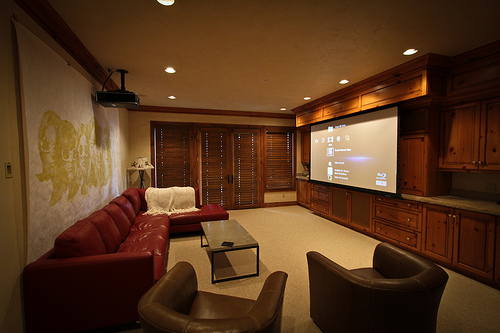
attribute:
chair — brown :
[279, 229, 476, 323]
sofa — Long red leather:
[21, 185, 227, 330]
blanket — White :
[144, 185, 199, 215]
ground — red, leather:
[398, 163, 441, 201]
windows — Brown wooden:
[149, 118, 296, 220]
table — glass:
[188, 216, 275, 282]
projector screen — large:
[305, 103, 402, 197]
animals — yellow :
[17, 52, 139, 222]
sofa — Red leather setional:
[15, 179, 233, 315]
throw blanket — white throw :
[139, 183, 203, 218]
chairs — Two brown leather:
[130, 234, 455, 331]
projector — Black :
[95, 67, 139, 109]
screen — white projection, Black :
[303, 117, 412, 194]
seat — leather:
[305, 238, 451, 330]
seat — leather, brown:
[137, 261, 291, 332]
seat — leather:
[19, 184, 227, 326]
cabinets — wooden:
[288, 52, 499, 287]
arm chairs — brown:
[135, 240, 449, 330]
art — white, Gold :
[20, 43, 129, 189]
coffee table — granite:
[198, 213, 268, 276]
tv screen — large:
[305, 105, 405, 205]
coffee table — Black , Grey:
[198, 214, 266, 282]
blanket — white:
[141, 186, 203, 216]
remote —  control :
[220, 240, 235, 247]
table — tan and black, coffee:
[184, 209, 275, 283]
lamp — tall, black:
[121, 147, 151, 197]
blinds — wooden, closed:
[154, 127, 291, 204]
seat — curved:
[132, 259, 284, 326]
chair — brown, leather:
[299, 233, 446, 328]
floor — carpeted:
[232, 204, 318, 264]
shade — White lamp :
[125, 145, 153, 172]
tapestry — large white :
[47, 119, 69, 182]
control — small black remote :
[220, 236, 235, 249]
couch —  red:
[23, 182, 223, 331]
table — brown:
[198, 215, 265, 283]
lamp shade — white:
[124, 155, 154, 170]